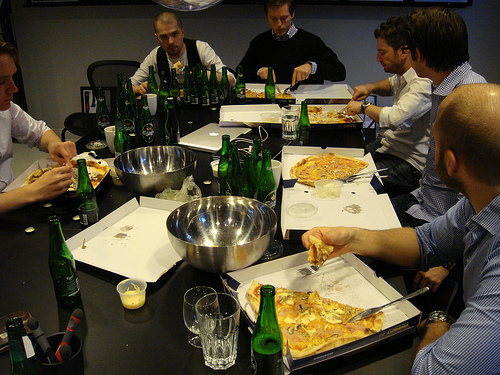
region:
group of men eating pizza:
[0, 2, 497, 370]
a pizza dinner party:
[0, 0, 498, 373]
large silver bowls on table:
[117, 143, 275, 274]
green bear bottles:
[45, 66, 310, 371]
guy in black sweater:
[237, 2, 348, 79]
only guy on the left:
[0, 38, 73, 219]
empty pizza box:
[67, 193, 197, 281]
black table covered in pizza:
[4, 70, 416, 372]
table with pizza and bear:
[4, 80, 421, 373]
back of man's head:
[434, 83, 499, 205]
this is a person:
[301, 83, 498, 366]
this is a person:
[402, 0, 499, 234]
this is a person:
[362, 22, 449, 210]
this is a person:
[250, 5, 325, 92]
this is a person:
[142, 20, 234, 140]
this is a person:
[0, 23, 75, 219]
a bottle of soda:
[232, 273, 294, 370]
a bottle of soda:
[35, 205, 95, 322]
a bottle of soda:
[62, 142, 117, 247]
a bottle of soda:
[231, 125, 279, 202]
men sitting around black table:
[5, 6, 495, 368]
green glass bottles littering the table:
[38, 62, 312, 372]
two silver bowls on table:
[109, 144, 271, 271]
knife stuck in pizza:
[350, 280, 435, 322]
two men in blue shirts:
[370, 17, 496, 373]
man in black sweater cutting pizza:
[235, 0, 338, 81]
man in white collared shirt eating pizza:
[340, 22, 447, 175]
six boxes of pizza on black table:
[28, 54, 417, 359]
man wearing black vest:
[120, 33, 234, 96]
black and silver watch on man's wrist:
[358, 97, 371, 119]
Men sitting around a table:
[0, 0, 498, 372]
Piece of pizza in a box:
[251, 282, 381, 360]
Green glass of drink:
[251, 282, 283, 374]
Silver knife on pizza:
[344, 289, 430, 323]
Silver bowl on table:
[166, 197, 276, 272]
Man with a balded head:
[433, 73, 498, 193]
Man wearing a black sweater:
[232, 3, 349, 84]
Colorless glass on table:
[198, 292, 243, 367]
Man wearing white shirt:
[345, 67, 430, 186]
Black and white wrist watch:
[359, 98, 373, 118]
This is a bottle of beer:
[45, 194, 100, 343]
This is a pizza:
[216, 176, 433, 373]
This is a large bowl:
[146, 139, 325, 323]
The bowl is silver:
[176, 164, 253, 285]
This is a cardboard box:
[299, 261, 407, 355]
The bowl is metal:
[146, 181, 223, 266]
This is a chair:
[41, 45, 153, 148]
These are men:
[146, 112, 457, 262]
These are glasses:
[150, 281, 222, 358]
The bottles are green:
[210, 263, 302, 373]